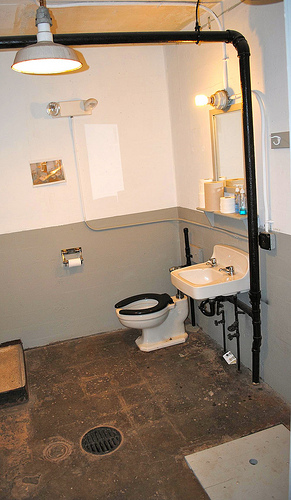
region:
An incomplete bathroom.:
[6, 72, 278, 493]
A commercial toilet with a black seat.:
[112, 284, 191, 350]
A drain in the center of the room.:
[63, 408, 159, 476]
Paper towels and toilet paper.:
[184, 172, 229, 213]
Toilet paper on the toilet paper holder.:
[56, 244, 90, 275]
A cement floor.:
[54, 339, 220, 426]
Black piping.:
[190, 296, 266, 389]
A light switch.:
[235, 219, 285, 254]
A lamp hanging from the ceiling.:
[6, 5, 81, 86]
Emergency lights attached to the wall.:
[20, 90, 117, 142]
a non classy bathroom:
[6, 4, 281, 451]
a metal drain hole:
[73, 420, 124, 459]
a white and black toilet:
[114, 290, 190, 351]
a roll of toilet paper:
[218, 194, 237, 214]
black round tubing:
[3, 24, 257, 90]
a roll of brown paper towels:
[203, 178, 223, 213]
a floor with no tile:
[26, 342, 250, 491]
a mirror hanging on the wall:
[197, 103, 259, 218]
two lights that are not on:
[45, 95, 103, 124]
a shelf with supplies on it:
[194, 176, 255, 234]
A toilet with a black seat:
[108, 289, 173, 350]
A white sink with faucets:
[171, 243, 248, 297]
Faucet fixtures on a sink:
[202, 250, 237, 279]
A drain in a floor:
[67, 416, 136, 470]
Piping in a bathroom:
[197, 294, 271, 388]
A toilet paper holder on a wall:
[51, 242, 93, 272]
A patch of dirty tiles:
[157, 378, 233, 430]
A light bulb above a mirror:
[182, 80, 238, 121]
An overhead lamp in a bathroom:
[10, 5, 92, 83]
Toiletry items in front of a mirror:
[194, 164, 254, 217]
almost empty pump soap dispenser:
[230, 181, 254, 219]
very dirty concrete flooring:
[170, 335, 245, 423]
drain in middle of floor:
[68, 417, 131, 462]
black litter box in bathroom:
[0, 332, 27, 407]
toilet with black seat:
[109, 266, 206, 360]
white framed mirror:
[192, 95, 265, 228]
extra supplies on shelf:
[196, 164, 255, 235]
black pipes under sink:
[167, 240, 273, 390]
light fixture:
[185, 81, 243, 110]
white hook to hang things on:
[267, 119, 290, 160]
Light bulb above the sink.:
[188, 87, 211, 111]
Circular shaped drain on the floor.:
[74, 418, 125, 456]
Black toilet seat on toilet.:
[112, 292, 172, 316]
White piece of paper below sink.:
[218, 351, 237, 365]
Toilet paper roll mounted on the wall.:
[60, 250, 86, 267]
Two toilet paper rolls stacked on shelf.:
[198, 173, 210, 208]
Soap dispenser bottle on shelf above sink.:
[233, 182, 247, 216]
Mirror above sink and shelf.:
[210, 110, 250, 210]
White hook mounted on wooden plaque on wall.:
[271, 132, 290, 148]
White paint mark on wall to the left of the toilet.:
[84, 123, 124, 199]